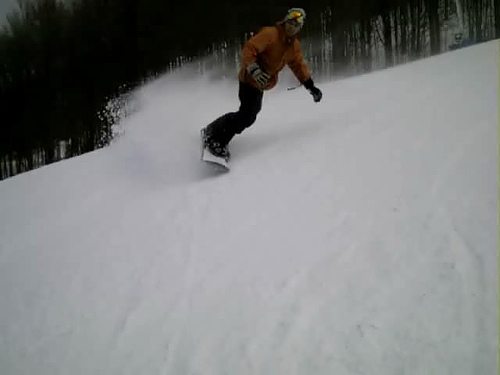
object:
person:
[201, 7, 321, 157]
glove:
[307, 85, 322, 103]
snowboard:
[201, 125, 232, 170]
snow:
[96, 52, 198, 146]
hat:
[276, 8, 307, 30]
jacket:
[237, 25, 313, 91]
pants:
[206, 78, 264, 145]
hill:
[2, 27, 495, 192]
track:
[4, 166, 491, 373]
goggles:
[286, 23, 301, 27]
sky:
[1, 3, 82, 34]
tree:
[380, 1, 395, 68]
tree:
[32, 2, 62, 166]